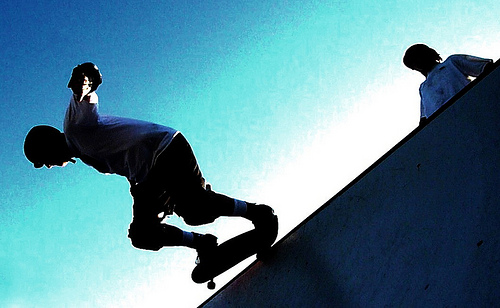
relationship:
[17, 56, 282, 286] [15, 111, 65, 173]
man wearing helmet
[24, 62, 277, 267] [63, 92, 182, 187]
man wearing shirt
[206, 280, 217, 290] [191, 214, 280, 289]
wheel of board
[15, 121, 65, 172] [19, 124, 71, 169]
helmet on head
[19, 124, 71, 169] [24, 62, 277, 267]
head of man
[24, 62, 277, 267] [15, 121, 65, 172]
man wearing helmet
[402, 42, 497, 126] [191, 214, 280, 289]
man watching board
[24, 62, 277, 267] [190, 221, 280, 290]
man on skateboard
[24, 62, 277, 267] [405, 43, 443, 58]
man wearing hat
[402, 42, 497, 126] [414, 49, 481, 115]
man wearing shirt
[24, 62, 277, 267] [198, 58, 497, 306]
man on halfpipe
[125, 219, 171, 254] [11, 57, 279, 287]
kneepad of skateboarder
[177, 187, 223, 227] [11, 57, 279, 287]
kneepad of skateboarder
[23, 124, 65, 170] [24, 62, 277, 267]
helmet of man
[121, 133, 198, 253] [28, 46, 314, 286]
shorts of skateboarder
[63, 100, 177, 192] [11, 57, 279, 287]
shirt of skateboarder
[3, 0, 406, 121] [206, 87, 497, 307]
sky above ramp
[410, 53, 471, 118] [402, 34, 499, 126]
shirt of man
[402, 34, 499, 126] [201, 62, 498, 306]
man standing on top of ramp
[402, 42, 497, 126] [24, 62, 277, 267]
man watching man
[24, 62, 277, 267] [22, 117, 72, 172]
man wearing helmet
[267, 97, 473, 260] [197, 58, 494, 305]
wall has edge